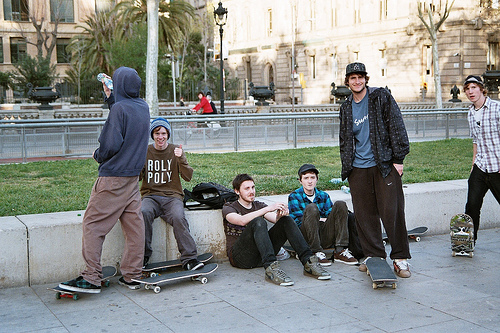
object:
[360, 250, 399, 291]
skateboard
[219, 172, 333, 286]
guy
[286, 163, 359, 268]
guy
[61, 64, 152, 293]
guy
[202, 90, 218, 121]
person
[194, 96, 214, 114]
shirt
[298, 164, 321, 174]
hat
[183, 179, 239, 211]
backpack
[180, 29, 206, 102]
trees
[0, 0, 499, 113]
background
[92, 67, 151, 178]
sweat shirt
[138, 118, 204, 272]
boy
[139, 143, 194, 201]
shirt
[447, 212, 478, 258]
skateboard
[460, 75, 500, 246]
boy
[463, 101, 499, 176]
shirt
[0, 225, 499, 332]
ground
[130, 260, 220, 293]
skateboard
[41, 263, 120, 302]
skateboard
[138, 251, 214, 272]
skateboard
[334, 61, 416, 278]
boy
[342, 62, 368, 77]
hat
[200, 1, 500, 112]
building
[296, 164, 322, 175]
cap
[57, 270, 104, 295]
sneakers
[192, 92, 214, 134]
bike rider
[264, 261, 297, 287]
tennis shoes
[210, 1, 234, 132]
lamp post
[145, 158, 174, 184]
roly poly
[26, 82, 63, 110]
sculpture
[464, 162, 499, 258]
pants